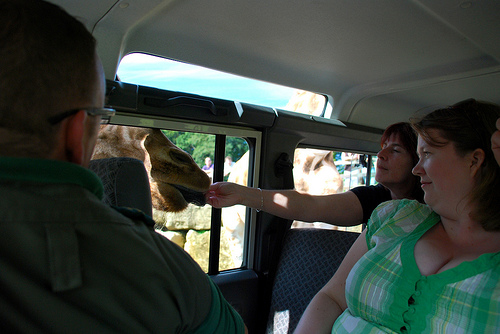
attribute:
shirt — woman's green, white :
[334, 187, 475, 320]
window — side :
[104, 116, 267, 281]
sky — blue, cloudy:
[183, 65, 204, 85]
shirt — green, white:
[367, 241, 461, 331]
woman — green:
[373, 104, 494, 323]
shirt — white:
[364, 254, 447, 330]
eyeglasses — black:
[72, 104, 119, 134]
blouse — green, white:
[349, 198, 459, 301]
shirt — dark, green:
[85, 258, 193, 303]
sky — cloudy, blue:
[157, 69, 208, 88]